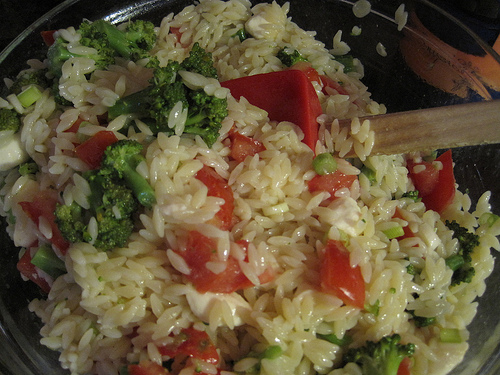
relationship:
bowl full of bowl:
[2, 6, 496, 374] [0, 0, 500, 375]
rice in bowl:
[0, 0, 500, 375] [15, 57, 493, 370]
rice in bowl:
[0, 0, 500, 375] [19, 29, 497, 367]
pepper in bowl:
[309, 167, 358, 204] [2, 6, 496, 374]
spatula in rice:
[280, 57, 467, 167] [155, 162, 280, 264]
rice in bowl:
[14, 22, 494, 373] [2, 6, 496, 374]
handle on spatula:
[325, 98, 499, 159] [199, 57, 496, 190]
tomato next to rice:
[313, 241, 368, 305] [236, 166, 321, 345]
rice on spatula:
[0, 0, 500, 375] [219, 71, 499, 156]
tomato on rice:
[313, 239, 368, 308] [24, 21, 461, 349]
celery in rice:
[12, 85, 46, 119] [14, 22, 494, 373]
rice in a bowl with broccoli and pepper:
[14, 22, 494, 373] [313, 232, 370, 307]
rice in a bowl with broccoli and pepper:
[14, 22, 494, 373] [222, 62, 327, 156]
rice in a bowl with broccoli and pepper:
[14, 22, 494, 373] [405, 147, 468, 211]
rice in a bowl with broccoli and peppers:
[14, 22, 494, 373] [177, 161, 279, 293]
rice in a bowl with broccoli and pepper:
[14, 22, 494, 373] [417, 146, 466, 214]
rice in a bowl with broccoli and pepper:
[14, 22, 494, 373] [231, 128, 266, 161]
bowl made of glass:
[2, 6, 496, 374] [403, 41, 489, 93]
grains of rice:
[261, 173, 303, 221] [88, 222, 204, 375]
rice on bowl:
[14, 22, 494, 373] [0, 0, 500, 375]